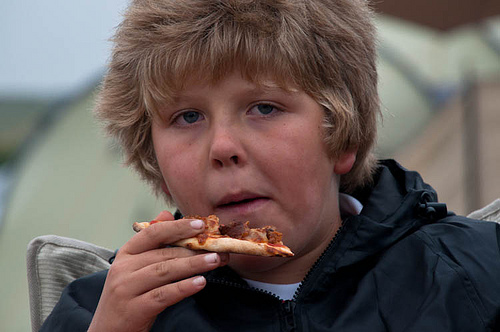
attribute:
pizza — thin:
[129, 212, 298, 260]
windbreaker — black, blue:
[38, 158, 488, 329]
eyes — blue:
[165, 102, 288, 124]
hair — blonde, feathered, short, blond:
[87, 2, 388, 206]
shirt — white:
[239, 192, 363, 302]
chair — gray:
[23, 195, 496, 327]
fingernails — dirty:
[212, 251, 220, 265]